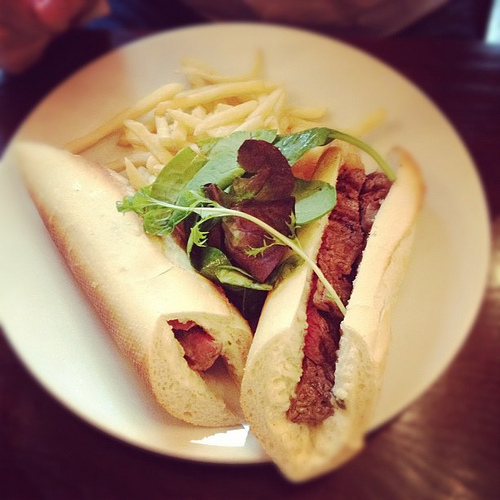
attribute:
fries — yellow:
[159, 89, 221, 132]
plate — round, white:
[0, 35, 498, 475]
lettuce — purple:
[253, 150, 278, 167]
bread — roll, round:
[38, 167, 94, 227]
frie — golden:
[72, 128, 116, 148]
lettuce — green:
[198, 158, 225, 181]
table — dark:
[423, 32, 473, 82]